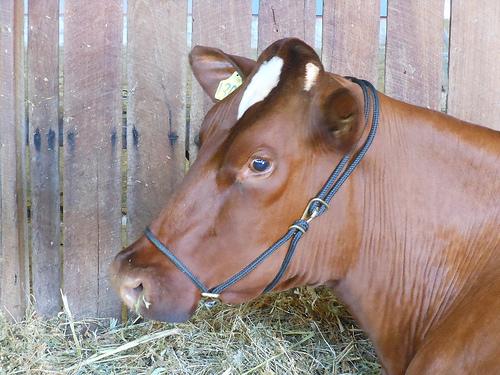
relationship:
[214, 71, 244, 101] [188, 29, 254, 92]
ear tag in cows ear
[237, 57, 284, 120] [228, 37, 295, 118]
pattern on forehead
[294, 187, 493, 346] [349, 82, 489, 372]
wrinkles on neck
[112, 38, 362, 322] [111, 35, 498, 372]
face of cow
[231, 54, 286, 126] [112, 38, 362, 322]
pattern on face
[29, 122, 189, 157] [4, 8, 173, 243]
stains on fence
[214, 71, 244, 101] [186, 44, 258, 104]
ear tag in ear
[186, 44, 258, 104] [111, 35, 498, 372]
ear of cow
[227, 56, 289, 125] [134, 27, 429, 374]
spot on cow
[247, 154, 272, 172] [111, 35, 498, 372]
eye of cow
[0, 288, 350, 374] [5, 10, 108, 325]
hay next to fence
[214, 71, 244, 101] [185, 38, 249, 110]
ear tag in ear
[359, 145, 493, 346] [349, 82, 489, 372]
wrinkles in neck